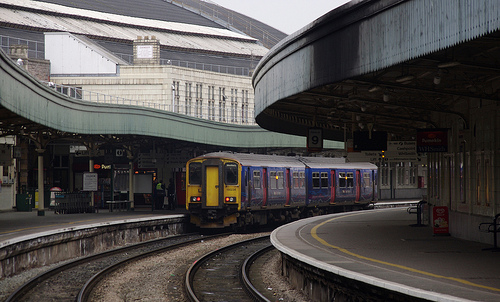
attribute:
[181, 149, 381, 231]
train — red, yellow, blue, small, short, silver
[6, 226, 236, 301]
track — dirty, black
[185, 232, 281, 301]
track — dirty, black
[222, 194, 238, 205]
lights — white, red, on, orange, little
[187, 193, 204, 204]
lights — white, red, on, orange, little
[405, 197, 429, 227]
bench — black, metal, long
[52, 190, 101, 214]
bench — black, metal, long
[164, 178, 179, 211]
person — standing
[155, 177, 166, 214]
person — standing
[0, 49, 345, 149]
roof — green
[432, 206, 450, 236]
posterboard — red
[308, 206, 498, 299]
line — yellow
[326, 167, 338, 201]
door — red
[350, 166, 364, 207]
door — red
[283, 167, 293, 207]
door — red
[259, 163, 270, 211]
door — red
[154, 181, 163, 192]
vest — green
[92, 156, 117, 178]
sign — hanging, white, red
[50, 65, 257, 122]
building — white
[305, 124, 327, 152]
sign — red, white, hanging, 9, black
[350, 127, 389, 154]
sign — hanging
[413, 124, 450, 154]
sign — hanging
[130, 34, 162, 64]
chimney — white, brick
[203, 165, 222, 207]
door — yellow